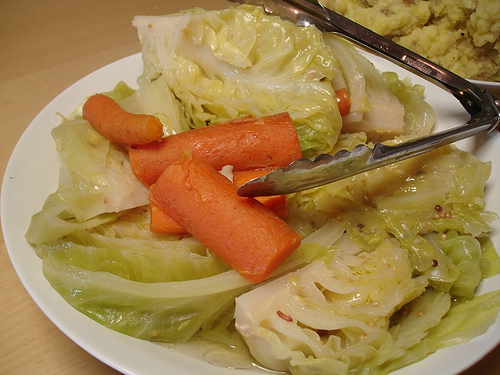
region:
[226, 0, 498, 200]
Silver tongs for handling food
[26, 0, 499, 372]
Seasoned boiled cabbage and carrots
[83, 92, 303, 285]
Cooked orange carrot segments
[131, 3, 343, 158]
Large piece of cooked cabbage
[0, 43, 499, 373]
Round white plate containing food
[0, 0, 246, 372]
Wood-grained table top beneath plate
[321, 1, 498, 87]
Dish of unidentified food in background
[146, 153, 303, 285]
Single piece of cooked carrot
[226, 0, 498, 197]
Food tongs laying on plate of food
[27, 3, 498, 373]
Healthy green and yellow cooked vegetable dish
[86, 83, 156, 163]
Piece of carrot on plate.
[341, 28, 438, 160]
Silver tongues on plate.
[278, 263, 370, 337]
Cooked cabbage on plate.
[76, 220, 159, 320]
Cooked cabbage on plate.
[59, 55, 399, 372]
Plate on table is white and round.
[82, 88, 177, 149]
Orange carrot on plate.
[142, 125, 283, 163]
Orange carrot on plate.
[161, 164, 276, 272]
Orange carrot on plate.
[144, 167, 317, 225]
Orange carrot on plate.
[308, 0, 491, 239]
Silver tongues on plate.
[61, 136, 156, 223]
Cooked cabbage sitting on plate.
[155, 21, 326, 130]
Cooked cabbage sitting on plate.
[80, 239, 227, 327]
Cooked cabbage sitting on plate.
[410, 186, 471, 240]
Cooked cabbage sitting on plate.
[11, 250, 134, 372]
White round plate sitting on table.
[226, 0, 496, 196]
the tongs resting on the food on the plate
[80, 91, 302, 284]
the pile of sliced carrots on the plate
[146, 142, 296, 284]
the piece of a carrot on the pile of cabbage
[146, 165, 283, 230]
the piece of a carrot on the pile of cabbage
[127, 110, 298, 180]
the piece of a carrot on the pile of cabbage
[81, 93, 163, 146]
the piece of carrot on the pile of cabbage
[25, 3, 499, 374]
the cabbage on the white plate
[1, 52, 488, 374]
the white plate under the food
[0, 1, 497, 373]
the table under the white plate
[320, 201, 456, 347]
the seasoning on the cabbage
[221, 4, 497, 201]
the tongs are leaning on the cabbage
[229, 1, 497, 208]
the tongs are silver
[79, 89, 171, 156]
a carrot is on top of the cabbage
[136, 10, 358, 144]
the cabbage is on top of a carrot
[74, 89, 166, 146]
the carrot is orange in color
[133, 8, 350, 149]
the cabbage is yellow green in color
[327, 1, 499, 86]
fried fish is in the background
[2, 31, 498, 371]
the plate holding the food is white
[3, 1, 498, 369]
the table is wood and the color is light tan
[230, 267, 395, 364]
the center of the cabbage is white